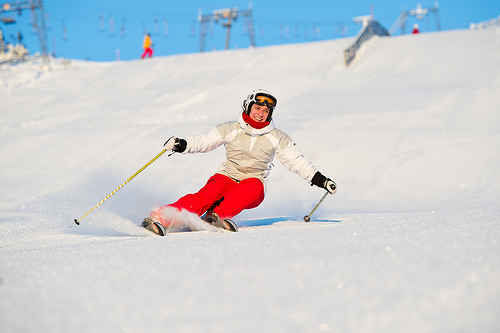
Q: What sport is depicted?
A: Skiing.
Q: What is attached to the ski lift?
A: Chairs are attached.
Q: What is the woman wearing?
A: Skiing gear.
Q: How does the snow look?
A: It is white.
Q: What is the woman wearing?
A: A jacket.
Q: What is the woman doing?
A: She is skiing.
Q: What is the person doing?
A: The person is skiing.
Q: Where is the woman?
A: On a ski slope.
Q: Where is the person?
A: At a ski resort.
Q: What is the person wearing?
A: Red ski pants.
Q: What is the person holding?
A: Ski poles.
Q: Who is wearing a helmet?
A: The boy.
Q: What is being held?
A: Ski poles.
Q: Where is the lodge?
A: In the distance.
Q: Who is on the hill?
A: The woman.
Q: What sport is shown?
A: Skiing.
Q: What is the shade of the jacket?
A: White.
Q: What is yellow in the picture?
A: The pole.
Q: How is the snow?
A: In the air.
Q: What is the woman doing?
A: Skiing.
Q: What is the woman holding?
A: Poles.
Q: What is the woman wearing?
A: Gloves.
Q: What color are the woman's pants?
A: Red.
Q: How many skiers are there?
A: One.